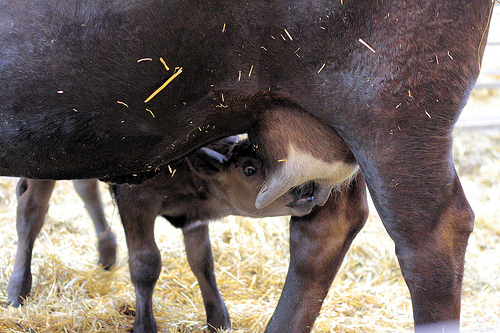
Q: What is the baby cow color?
A: Brown.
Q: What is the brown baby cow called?
A: A calf.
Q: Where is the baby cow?
A: Under the mother.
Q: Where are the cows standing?
A: In hay.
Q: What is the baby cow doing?
A: Getting milk from his mom.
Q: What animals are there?
A: Cows.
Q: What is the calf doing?
A: Drinking milk.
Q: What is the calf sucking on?
A: Udder.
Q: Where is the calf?
A: Under the cow.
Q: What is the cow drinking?
A: Milk.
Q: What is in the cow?
A: Grass and hay.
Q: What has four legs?
A: Calves.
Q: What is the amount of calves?
A: One.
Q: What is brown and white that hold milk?
A: The udders.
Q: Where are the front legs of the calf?
A: In the straw.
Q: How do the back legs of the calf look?
A: Spread apart.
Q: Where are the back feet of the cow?
A: Next to the calf.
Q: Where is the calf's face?
A: By the mother's teats.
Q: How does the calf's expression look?
A: Surprised.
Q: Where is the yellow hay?
A: Under the cow and calf.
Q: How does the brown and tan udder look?
A: Covered in hair.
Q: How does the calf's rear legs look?
A: Spread apart.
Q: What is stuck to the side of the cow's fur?
A: Bits of straw.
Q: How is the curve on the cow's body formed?
A: By thigh and underbelly.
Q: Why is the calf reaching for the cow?
A: To drink.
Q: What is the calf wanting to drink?
A: Milk.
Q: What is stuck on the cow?
A: Straw.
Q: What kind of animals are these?
A: Cows.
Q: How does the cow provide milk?
A: Through the utter.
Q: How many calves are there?
A: One.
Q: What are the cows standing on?
A: Straw.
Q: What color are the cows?
A: Brown.